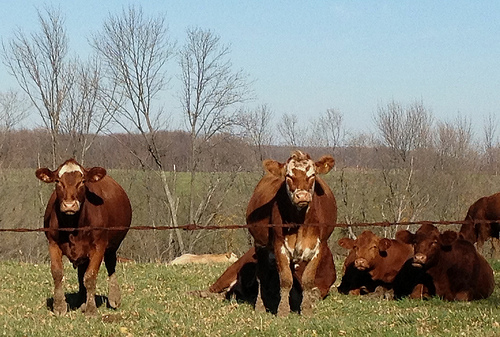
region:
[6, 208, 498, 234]
line of barbed wire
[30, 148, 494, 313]
cows behind barbed wire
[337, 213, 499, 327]
cows sitting on grass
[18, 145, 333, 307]
brown and white cows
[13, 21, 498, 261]
line of trees without leaves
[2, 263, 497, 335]
grass field with leaves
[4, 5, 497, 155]
blue cloudless sky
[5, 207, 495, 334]
meadow behind barbed wire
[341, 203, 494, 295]
dark brown cows lying down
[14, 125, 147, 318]
cow looking at camera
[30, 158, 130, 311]
the cow is looking head on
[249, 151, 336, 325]
the cow is facing front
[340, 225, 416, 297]
a cow is resting on the grass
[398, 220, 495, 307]
a cow is resting on the grass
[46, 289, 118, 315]
a shadow is on the grass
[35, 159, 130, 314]
the cow is casting a shadow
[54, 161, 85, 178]
the cow has a white patch on her head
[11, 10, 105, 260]
the tree on the background is bare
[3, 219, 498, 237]
a wire is in the foreground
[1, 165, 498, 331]
the field is filled with grass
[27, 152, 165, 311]
Brown and white cow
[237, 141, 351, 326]
Second brown and white cow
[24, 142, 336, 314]
Two cows standing in the field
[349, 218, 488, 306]
Two cows laying down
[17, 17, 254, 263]
Group of bare trees in the field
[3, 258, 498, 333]
Green grass field for cows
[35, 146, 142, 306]
Cow looking towards camera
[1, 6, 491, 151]
Beautiful blue sky without clouds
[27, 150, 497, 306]
Group of cows in the field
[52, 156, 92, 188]
White spot on brown cows face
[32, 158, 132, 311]
Brown cow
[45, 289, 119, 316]
Shadow of the brown cow on the ground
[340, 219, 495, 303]
Group of brown cows laying down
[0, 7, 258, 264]
Couple of tree branches near the cow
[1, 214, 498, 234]
Thin wire in front of the cows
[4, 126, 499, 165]
Forest land distant from the cows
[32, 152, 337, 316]
Couple of cows standing still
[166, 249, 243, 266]
Large twig by the tree branch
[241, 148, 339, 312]
Adult cow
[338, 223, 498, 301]
Couple of baby cows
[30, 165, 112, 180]
The ears of the cow on the left.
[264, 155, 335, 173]
The ears of the cow in the middle.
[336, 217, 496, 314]
The two cows sitting on the ground.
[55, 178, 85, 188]
The eyes of the cow on the left.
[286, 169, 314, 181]
The eyes of the cow in the middle.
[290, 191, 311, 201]
The nose of the cow in the middle.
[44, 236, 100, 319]
The front legs of the cow on the left.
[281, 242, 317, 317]
The front legs of the cow in the middle.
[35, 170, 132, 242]
The body of the cow on the left.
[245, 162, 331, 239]
The body of the cow in the middle.